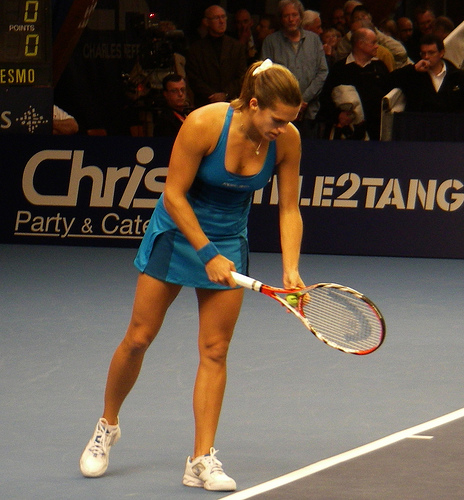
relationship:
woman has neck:
[79, 58, 303, 492] [242, 104, 263, 138]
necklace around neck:
[239, 107, 264, 156] [242, 104, 263, 138]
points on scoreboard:
[23, 33, 39, 56] [0, 1, 55, 86]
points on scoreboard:
[23, 0, 39, 22] [0, 1, 55, 86]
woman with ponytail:
[79, 58, 303, 492] [231, 60, 271, 113]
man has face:
[154, 73, 188, 136] [165, 80, 186, 107]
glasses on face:
[164, 87, 185, 93] [165, 80, 186, 107]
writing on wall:
[14, 211, 150, 240] [0, 132, 463, 261]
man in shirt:
[259, 0, 329, 137] [260, 30, 328, 120]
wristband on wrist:
[196, 240, 219, 263] [196, 240, 218, 264]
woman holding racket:
[79, 58, 303, 492] [231, 271, 385, 355]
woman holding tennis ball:
[79, 58, 303, 492] [285, 286, 307, 309]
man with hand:
[378, 36, 463, 115] [413, 58, 430, 71]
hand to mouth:
[413, 58, 430, 71] [423, 61, 430, 65]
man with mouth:
[378, 36, 463, 115] [423, 61, 430, 65]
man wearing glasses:
[185, 5, 247, 109] [204, 13, 229, 21]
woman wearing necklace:
[79, 58, 303, 492] [239, 107, 264, 156]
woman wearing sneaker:
[79, 58, 303, 492] [183, 447, 238, 491]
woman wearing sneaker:
[79, 58, 303, 492] [78, 416, 120, 477]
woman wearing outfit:
[79, 58, 303, 492] [134, 103, 274, 289]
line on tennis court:
[219, 407, 463, 498] [0, 244, 462, 499]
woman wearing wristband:
[79, 58, 303, 492] [196, 240, 219, 263]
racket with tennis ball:
[231, 271, 385, 355] [285, 286, 307, 309]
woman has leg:
[79, 58, 303, 492] [102, 272, 182, 425]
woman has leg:
[79, 58, 303, 492] [194, 286, 243, 458]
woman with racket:
[79, 58, 303, 492] [231, 271, 385, 355]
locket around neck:
[256, 150, 260, 156] [242, 104, 263, 138]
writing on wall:
[21, 145, 169, 209] [0, 132, 463, 261]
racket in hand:
[231, 271, 385, 355] [205, 255, 236, 288]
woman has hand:
[79, 58, 303, 492] [205, 255, 236, 288]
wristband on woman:
[196, 240, 219, 263] [79, 58, 303, 492]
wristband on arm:
[196, 240, 219, 263] [162, 124, 222, 266]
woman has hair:
[79, 58, 303, 492] [230, 60, 301, 114]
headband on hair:
[251, 57, 273, 74] [230, 60, 301, 114]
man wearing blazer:
[185, 5, 247, 109] [185, 34, 247, 104]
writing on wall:
[252, 173, 463, 212] [0, 132, 463, 261]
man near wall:
[154, 73, 188, 136] [0, 132, 463, 261]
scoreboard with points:
[0, 1, 55, 86] [23, 33, 39, 56]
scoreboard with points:
[0, 1, 55, 86] [23, 0, 39, 22]